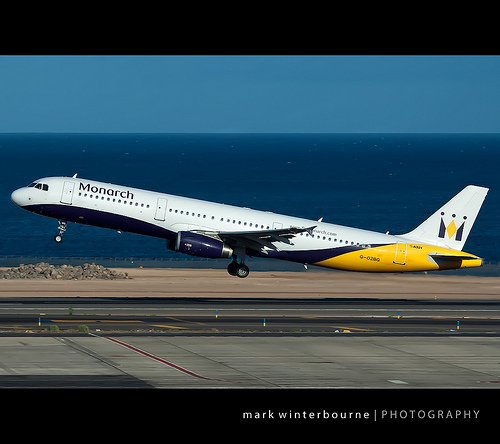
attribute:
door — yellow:
[390, 239, 413, 265]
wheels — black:
[222, 245, 256, 288]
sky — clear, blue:
[0, 57, 484, 129]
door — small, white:
[57, 179, 80, 209]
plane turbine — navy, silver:
[6, 153, 484, 277]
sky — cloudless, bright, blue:
[0, 62, 477, 135]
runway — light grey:
[1, 334, 470, 389]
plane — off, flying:
[11, 171, 489, 276]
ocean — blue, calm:
[1, 133, 500, 262]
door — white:
[60, 182, 75, 207]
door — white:
[272, 224, 282, 234]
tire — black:
[54, 233, 64, 243]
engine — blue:
[170, 231, 233, 257]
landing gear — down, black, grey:
[222, 244, 253, 277]